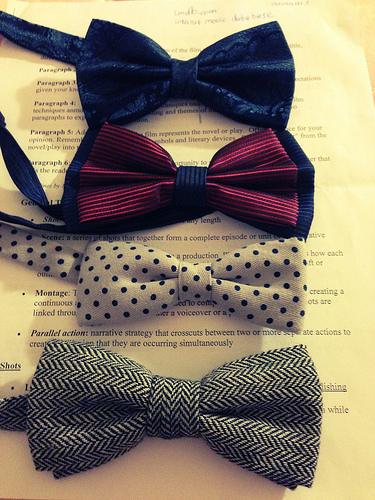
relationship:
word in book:
[30, 327, 62, 336] [1, 0, 372, 499]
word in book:
[33, 287, 68, 297] [1, 0, 372, 499]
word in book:
[28, 128, 66, 135] [1, 0, 372, 499]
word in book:
[317, 153, 331, 162] [1, 0, 372, 499]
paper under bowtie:
[5, 2, 373, 495] [2, 7, 300, 129]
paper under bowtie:
[5, 2, 373, 495] [1, 116, 319, 241]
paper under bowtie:
[5, 2, 373, 495] [0, 222, 310, 343]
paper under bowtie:
[5, 2, 373, 495] [5, 332, 331, 493]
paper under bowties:
[5, 2, 373, 495] [4, 5, 365, 491]